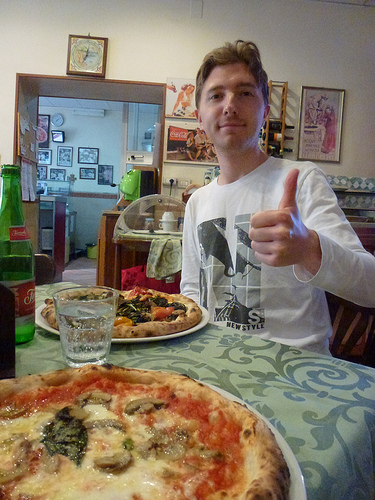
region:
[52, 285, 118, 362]
clear glass cu with clear liquid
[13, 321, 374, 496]
gray table cloth with darker gray designs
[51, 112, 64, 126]
round white wall clock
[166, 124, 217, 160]
Coca Cola poster on the wall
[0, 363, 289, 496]
pizza with mushrooms and spinach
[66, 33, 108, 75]
square wall clock above the doorway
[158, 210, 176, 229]
two stacked white cups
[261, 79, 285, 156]
wooden wine rack on the wall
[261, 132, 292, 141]
wine bottle with white and orange label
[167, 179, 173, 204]
black cord plugged into the wall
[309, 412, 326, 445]
part of a cloth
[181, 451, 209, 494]
part of a pizza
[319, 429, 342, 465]
edge of a table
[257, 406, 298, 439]
edge of a pizza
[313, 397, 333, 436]
part of a cloth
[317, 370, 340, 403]
part of a cloth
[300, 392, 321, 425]
part of a table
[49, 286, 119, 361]
Cup of sparkly substance in a glass.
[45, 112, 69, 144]
Cup of sparkly substance in a glass.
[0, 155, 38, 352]
Cup of sparkly substance in a glass.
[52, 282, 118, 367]
glass of sparkling water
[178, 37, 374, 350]
man giving a thumbs up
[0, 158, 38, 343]
green bottle of sparkling water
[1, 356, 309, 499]
large pizza on table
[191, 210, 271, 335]
logo design on a white tshirt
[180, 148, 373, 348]
man wearing a white tshirt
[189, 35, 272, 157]
man with short brown hair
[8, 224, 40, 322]
red labels on bottle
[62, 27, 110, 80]
picture hanging on wall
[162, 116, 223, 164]
vintage coca cola poster on wall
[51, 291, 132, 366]
One small crystal glass cup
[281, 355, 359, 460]
Table cloth in green and other colors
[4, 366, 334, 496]
One round pizza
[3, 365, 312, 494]
Round pizza with red sauce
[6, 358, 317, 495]
Round pizza with red sauce and white cheese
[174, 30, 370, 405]
Male holding thumb up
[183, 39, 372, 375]
Male smiling at camera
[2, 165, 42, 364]
Large green bottle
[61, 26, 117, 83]
Square picture on wall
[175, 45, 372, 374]
Guy smiling in white shirt